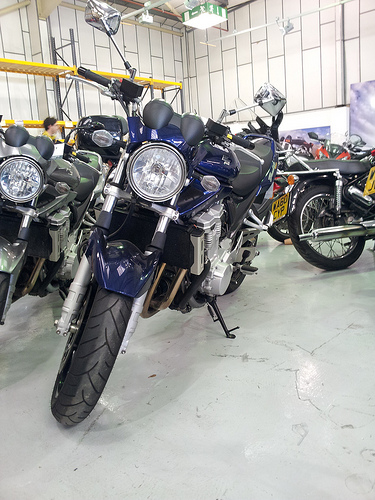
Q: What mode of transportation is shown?
A: Motorcycles.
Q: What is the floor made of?
A: Concrete.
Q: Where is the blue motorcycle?
A: Closest to the camera.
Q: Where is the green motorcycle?
A: Beside the blue motorcycle.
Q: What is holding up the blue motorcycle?
A: Kickstand.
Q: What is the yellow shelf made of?
A: Metal.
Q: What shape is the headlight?
A: Round.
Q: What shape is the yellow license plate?
A: Rectangle.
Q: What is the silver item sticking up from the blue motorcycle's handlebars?
A: Mirror.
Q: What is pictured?
A: Motorcycles.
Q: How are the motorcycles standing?
A: Motorcycle stands.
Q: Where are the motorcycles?
A: Inside a building.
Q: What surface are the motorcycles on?
A: Concrete.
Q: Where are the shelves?
A: Against the wall.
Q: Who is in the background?
A: A person.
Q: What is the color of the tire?
A: Black.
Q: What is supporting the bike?
A: Kickstand.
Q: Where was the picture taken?
A: In a garage.